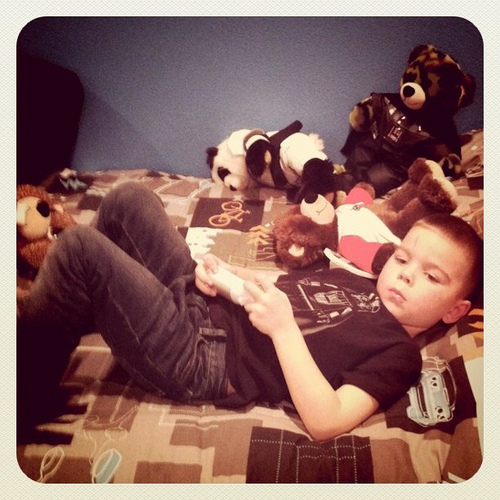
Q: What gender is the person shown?
A: Male.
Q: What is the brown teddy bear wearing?
A: A white and pink shirt.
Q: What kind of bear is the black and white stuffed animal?
A: A panda.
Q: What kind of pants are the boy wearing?
A: Jeans.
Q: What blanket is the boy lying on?
A: A tan and brown bedspread.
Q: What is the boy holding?
A: A game controller.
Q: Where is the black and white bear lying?
A: On its side.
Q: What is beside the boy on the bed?
A: Stuffed animals.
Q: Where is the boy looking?
A: Down.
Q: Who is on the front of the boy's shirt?
A: Darth Vader.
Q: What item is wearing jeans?
A: The boy.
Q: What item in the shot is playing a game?
A: The boy.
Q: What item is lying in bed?
A: One boy.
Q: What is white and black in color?
A: The panda.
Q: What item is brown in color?
A: The bed sheet.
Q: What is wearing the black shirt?
A: The boy.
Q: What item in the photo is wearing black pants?
A: The boy.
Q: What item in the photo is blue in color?
A: The wall.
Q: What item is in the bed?
A: The panda.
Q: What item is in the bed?
A: Three teddy.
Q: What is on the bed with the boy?
A: Stuffed animals.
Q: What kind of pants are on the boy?
A: Jeans.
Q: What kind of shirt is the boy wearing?
A: A black t-shirt.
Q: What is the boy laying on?
A: A bed.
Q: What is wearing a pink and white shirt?
A: A teddy bear.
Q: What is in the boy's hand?
A: A game controller.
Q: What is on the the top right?
A: A teddy bear.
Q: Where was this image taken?
A: A bedroom.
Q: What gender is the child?
A: Male.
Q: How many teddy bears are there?
A: Four.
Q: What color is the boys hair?
A: Brown.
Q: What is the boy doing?
A: Lying down.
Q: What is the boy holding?
A: A controller.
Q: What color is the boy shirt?
A: Black.